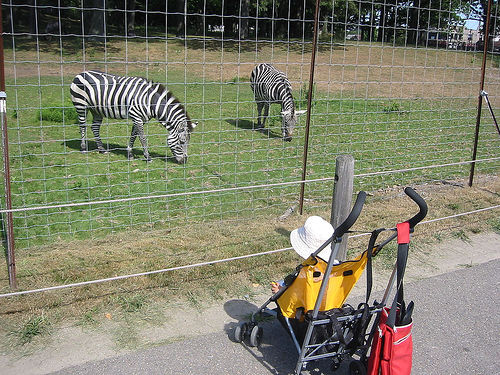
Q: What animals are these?
A: Zebras.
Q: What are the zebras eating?
A: Grass.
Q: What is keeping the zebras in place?
A: Fence.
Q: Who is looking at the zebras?
A: Baby.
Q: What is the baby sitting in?
A: Stroller.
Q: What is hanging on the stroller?
A: Bag.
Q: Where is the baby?
A: In the stroller.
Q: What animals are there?
A: Zebras.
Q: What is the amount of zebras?
A: Two.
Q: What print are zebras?
A: Striped.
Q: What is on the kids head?
A: Hat.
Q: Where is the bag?
A: Back of the stroller.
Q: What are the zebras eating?
A: Grass.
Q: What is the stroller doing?
A: Parked.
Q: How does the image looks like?
A: Good.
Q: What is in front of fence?
A: Double line rope.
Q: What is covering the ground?
A: Green grass.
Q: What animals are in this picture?
A: Zebra's.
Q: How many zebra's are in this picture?
A: Two.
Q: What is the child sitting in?
A: A stroller.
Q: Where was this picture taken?
A: A zoo.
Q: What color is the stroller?
A: Yellow.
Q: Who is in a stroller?
A: A child.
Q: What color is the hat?
A: White.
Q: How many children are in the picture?
A: One.